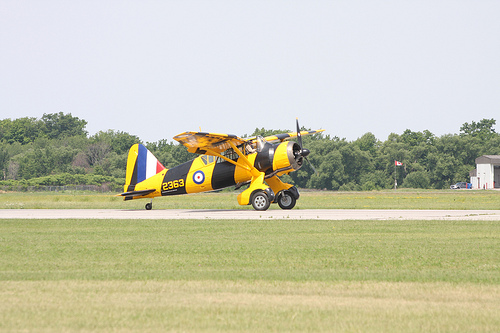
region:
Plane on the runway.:
[88, 112, 335, 211]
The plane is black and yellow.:
[126, 119, 328, 199]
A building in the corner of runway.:
[423, 147, 499, 187]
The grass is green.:
[103, 212, 434, 297]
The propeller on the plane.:
[286, 124, 313, 171]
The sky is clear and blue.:
[27, 13, 461, 83]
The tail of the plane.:
[116, 134, 173, 182]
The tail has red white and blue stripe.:
[128, 132, 164, 176]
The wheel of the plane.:
[250, 187, 301, 207]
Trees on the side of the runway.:
[9, 117, 147, 204]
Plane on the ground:
[111, 109, 323, 216]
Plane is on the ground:
[112, 115, 327, 222]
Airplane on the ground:
[110, 109, 323, 220]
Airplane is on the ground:
[110, 110, 324, 220]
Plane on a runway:
[110, 117, 324, 212]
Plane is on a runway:
[114, 112, 327, 217]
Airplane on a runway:
[108, 113, 326, 219]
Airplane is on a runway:
[110, 109, 327, 215]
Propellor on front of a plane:
[285, 112, 324, 185]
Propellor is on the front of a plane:
[278, 120, 330, 185]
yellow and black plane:
[106, 110, 319, 235]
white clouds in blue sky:
[371, 43, 408, 66]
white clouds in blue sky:
[420, 52, 453, 87]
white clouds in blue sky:
[354, 64, 384, 85]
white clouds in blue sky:
[241, 6, 291, 57]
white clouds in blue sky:
[247, 28, 307, 70]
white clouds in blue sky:
[287, 53, 312, 98]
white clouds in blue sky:
[127, 40, 162, 70]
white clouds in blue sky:
[129, 41, 197, 85]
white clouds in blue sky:
[91, 49, 127, 84]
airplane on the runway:
[90, 114, 320, 222]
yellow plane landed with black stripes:
[105, 111, 320, 228]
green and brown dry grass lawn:
[136, 227, 337, 325]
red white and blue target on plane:
[186, 165, 212, 186]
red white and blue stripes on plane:
[135, 145, 167, 179]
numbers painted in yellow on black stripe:
[156, 174, 190, 195]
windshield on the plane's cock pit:
[241, 134, 272, 158]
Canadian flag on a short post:
[388, 152, 414, 199]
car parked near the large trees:
[443, 170, 470, 202]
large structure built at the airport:
[471, 146, 498, 196]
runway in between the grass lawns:
[100, 192, 357, 248]